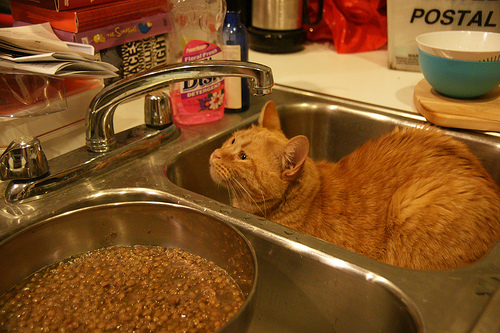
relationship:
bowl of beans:
[0, 198, 262, 331] [83, 244, 190, 301]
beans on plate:
[83, 244, 169, 300] [0, 187, 271, 332]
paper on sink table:
[0, 18, 122, 84] [1, 34, 499, 331]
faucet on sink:
[181, 47, 283, 109] [132, 102, 475, 247]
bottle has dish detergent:
[163, 0, 231, 130] [175, 79, 226, 121]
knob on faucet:
[2, 133, 52, 180] [0, 48, 278, 205]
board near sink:
[402, 72, 497, 133] [11, 36, 345, 261]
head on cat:
[199, 94, 309, 206] [173, 78, 497, 275]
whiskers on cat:
[211, 161, 260, 210] [204, 99, 497, 270]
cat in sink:
[204, 99, 497, 270] [4, 75, 497, 331]